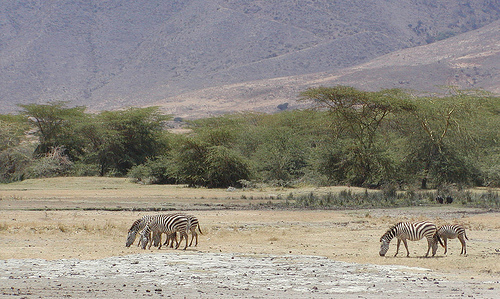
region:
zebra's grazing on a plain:
[113, 201, 497, 291]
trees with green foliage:
[5, 78, 496, 189]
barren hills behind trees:
[3, 3, 499, 175]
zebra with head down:
[376, 217, 439, 262]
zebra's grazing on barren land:
[13, 210, 496, 297]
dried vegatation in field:
[4, 208, 120, 258]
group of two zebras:
[373, 216, 472, 258]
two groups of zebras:
[117, 201, 497, 296]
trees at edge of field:
[4, 93, 229, 205]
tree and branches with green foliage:
[310, 73, 404, 192]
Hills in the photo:
[150, 37, 262, 101]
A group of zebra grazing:
[124, 204, 213, 256]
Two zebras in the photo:
[363, 201, 474, 263]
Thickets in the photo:
[225, 96, 408, 168]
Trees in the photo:
[168, 87, 377, 172]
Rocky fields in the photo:
[195, 248, 331, 285]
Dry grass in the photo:
[236, 223, 324, 246]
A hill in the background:
[91, 30, 232, 87]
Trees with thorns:
[44, 101, 214, 175]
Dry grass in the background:
[30, 217, 106, 237]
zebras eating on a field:
[103, 198, 475, 266]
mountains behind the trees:
[0, 4, 487, 197]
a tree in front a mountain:
[305, 70, 407, 175]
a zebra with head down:
[371, 213, 444, 264]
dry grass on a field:
[10, 193, 499, 258]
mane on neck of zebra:
[377, 212, 404, 242]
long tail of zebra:
[193, 220, 206, 237]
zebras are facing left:
[112, 200, 478, 267]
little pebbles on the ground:
[25, 258, 424, 298]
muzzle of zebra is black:
[371, 244, 390, 259]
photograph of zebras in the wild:
[22, 34, 474, 276]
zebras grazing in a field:
[81, 188, 470, 268]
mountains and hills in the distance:
[27, 0, 439, 87]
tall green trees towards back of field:
[1, 93, 468, 180]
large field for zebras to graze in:
[5, 179, 467, 280]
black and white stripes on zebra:
[405, 223, 421, 238]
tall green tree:
[304, 70, 415, 179]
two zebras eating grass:
[374, 210, 470, 260]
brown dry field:
[10, 210, 490, 291]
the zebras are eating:
[116, 208, 156, 253]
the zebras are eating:
[364, 202, 407, 267]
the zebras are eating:
[113, 205, 183, 260]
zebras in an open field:
[101, 198, 245, 283]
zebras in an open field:
[347, 198, 499, 280]